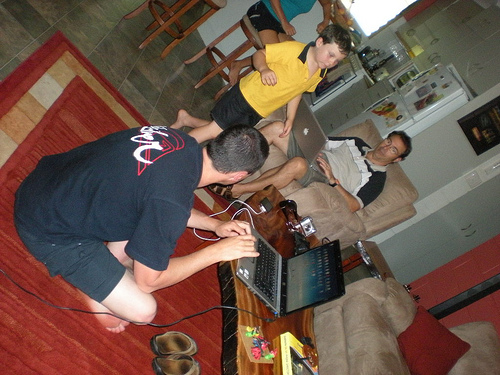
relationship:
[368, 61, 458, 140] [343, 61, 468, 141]
stuff hanging on doors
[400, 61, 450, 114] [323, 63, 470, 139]
magnets on refrigerator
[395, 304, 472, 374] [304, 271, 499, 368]
pillow on couch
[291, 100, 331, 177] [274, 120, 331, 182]
computer on lap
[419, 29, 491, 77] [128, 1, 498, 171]
cabinet in kitchen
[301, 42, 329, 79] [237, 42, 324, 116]
collar on shirt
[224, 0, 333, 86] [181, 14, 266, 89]
mom on bar stool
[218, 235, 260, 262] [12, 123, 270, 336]
hand on guy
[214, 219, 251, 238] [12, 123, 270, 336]
hand on guy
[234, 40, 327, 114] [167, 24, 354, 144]
shirt on son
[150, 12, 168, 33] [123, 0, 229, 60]
wood on wood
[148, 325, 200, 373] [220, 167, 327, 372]
shoes under coffee table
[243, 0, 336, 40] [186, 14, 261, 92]
mom on bar stool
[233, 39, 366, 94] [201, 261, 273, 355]
son approaches table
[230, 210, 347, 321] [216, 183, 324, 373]
laptop on coffee table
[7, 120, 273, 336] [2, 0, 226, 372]
guy on floor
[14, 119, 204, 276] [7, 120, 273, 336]
black shirt on guy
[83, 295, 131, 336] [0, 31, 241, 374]
foot on carpet